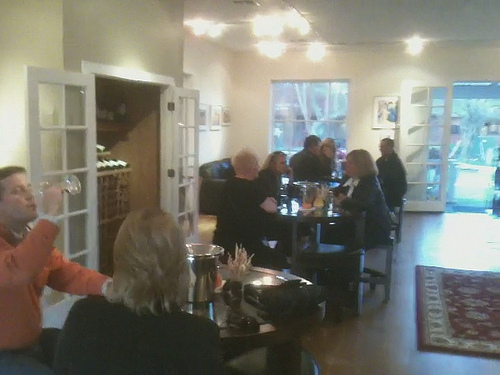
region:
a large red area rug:
[408, 266, 498, 354]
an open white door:
[25, 70, 100, 326]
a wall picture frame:
[210, 105, 222, 132]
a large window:
[272, 79, 344, 155]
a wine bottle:
[115, 155, 128, 167]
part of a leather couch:
[196, 152, 236, 209]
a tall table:
[269, 198, 369, 315]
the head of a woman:
[110, 200, 193, 320]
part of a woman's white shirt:
[340, 173, 359, 195]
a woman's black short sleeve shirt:
[214, 177, 270, 236]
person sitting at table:
[376, 130, 409, 204]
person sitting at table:
[343, 147, 390, 218]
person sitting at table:
[226, 141, 272, 223]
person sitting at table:
[93, 220, 213, 370]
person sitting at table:
[5, 165, 91, 325]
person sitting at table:
[268, 145, 287, 183]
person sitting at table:
[295, 132, 318, 169]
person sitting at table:
[323, 135, 331, 160]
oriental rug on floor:
[406, 256, 495, 361]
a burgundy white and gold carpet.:
[406, 250, 497, 361]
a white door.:
[399, 77, 459, 216]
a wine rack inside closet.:
[97, 87, 142, 223]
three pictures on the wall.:
[190, 95, 237, 135]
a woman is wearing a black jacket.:
[68, 307, 204, 372]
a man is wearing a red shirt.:
[1, 230, 56, 349]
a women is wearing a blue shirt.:
[340, 180, 399, 230]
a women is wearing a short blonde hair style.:
[229, 145, 262, 183]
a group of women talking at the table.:
[204, 149, 411, 279]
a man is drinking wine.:
[1, 146, 61, 331]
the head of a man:
[0, 164, 43, 226]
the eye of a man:
[8, 183, 25, 196]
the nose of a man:
[20, 185, 35, 205]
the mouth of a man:
[24, 197, 41, 212]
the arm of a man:
[0, 211, 62, 290]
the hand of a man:
[36, 185, 68, 217]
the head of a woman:
[340, 144, 385, 183]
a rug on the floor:
[408, 259, 499, 357]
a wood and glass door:
[395, 80, 451, 214]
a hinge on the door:
[162, 97, 179, 114]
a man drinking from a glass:
[5, 164, 79, 236]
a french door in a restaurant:
[36, 82, 103, 300]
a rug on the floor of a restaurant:
[417, 264, 497, 351]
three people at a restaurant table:
[231, 143, 383, 264]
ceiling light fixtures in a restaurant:
[207, 10, 430, 74]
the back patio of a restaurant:
[426, 85, 496, 207]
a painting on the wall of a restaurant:
[370, 90, 411, 136]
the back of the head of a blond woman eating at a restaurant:
[103, 208, 318, 358]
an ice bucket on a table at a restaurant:
[185, 236, 228, 311]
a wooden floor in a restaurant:
[335, 327, 405, 366]